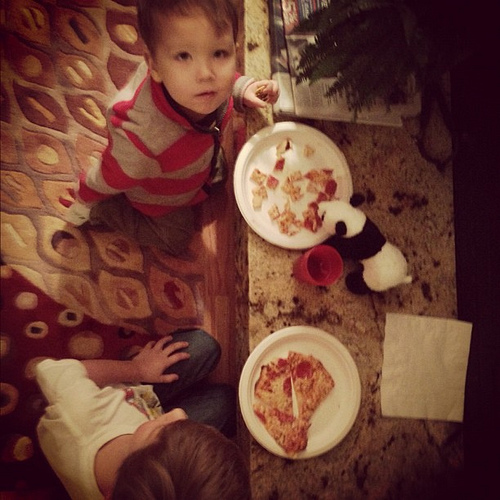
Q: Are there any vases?
A: No, there are no vases.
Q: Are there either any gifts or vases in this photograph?
A: No, there are no vases or gifts.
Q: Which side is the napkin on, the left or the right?
A: The napkin is on the right of the image.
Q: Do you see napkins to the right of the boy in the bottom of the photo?
A: Yes, there is a napkin to the right of the boy.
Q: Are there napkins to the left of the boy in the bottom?
A: No, the napkin is to the right of the boy.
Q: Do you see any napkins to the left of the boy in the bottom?
A: No, the napkin is to the right of the boy.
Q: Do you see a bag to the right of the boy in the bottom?
A: No, there is a napkin to the right of the boy.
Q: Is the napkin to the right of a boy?
A: Yes, the napkin is to the right of a boy.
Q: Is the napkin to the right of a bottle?
A: No, the napkin is to the right of a boy.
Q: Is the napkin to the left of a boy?
A: No, the napkin is to the right of a boy.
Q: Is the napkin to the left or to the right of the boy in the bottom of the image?
A: The napkin is to the right of the boy.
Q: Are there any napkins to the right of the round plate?
A: Yes, there is a napkin to the right of the plate.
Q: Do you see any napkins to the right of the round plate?
A: Yes, there is a napkin to the right of the plate.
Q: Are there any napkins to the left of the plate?
A: No, the napkin is to the right of the plate.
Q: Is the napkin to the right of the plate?
A: Yes, the napkin is to the right of the plate.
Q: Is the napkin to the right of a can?
A: No, the napkin is to the right of the plate.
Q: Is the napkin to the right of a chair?
A: No, the napkin is to the right of a pizza slice.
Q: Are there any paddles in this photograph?
A: No, there are no paddles.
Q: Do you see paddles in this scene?
A: No, there are no paddles.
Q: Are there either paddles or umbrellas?
A: No, there are no paddles or umbrellas.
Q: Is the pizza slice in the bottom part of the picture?
A: Yes, the pizza slice is in the bottom of the image.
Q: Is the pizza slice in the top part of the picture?
A: No, the pizza slice is in the bottom of the image.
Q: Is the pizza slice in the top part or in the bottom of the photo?
A: The pizza slice is in the bottom of the image.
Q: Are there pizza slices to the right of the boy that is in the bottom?
A: Yes, there is a pizza slice to the right of the boy.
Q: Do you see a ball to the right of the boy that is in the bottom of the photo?
A: No, there is a pizza slice to the right of the boy.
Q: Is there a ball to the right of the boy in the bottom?
A: No, there is a pizza slice to the right of the boy.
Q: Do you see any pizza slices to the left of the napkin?
A: Yes, there is a pizza slice to the left of the napkin.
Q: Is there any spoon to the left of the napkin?
A: No, there is a pizza slice to the left of the napkin.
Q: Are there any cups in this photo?
A: Yes, there is a cup.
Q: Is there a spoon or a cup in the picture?
A: Yes, there is a cup.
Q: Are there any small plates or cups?
A: Yes, there is a small cup.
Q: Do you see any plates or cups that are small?
A: Yes, the cup is small.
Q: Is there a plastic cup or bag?
A: Yes, there is a plastic cup.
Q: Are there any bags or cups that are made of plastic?
A: Yes, the cup is made of plastic.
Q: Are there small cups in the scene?
A: Yes, there is a small cup.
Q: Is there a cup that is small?
A: Yes, there is a cup that is small.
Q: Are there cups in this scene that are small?
A: Yes, there is a cup that is small.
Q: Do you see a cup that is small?
A: Yes, there is a cup that is small.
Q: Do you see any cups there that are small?
A: Yes, there is a cup that is small.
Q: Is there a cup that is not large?
A: Yes, there is a small cup.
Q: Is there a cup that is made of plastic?
A: Yes, there is a cup that is made of plastic.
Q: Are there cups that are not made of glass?
A: Yes, there is a cup that is made of plastic.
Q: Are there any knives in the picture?
A: No, there are no knives.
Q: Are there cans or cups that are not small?
A: No, there is a cup but it is small.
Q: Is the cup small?
A: Yes, the cup is small.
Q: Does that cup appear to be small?
A: Yes, the cup is small.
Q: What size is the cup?
A: The cup is small.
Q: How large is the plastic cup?
A: The cup is small.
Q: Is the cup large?
A: No, the cup is small.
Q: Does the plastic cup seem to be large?
A: No, the cup is small.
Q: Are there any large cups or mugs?
A: No, there is a cup but it is small.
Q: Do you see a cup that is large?
A: No, there is a cup but it is small.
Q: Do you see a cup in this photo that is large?
A: No, there is a cup but it is small.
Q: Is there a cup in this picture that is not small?
A: No, there is a cup but it is small.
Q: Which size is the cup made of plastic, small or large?
A: The cup is small.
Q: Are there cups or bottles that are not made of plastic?
A: No, there is a cup but it is made of plastic.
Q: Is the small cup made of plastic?
A: Yes, the cup is made of plastic.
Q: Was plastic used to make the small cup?
A: Yes, the cup is made of plastic.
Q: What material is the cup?
A: The cup is made of plastic.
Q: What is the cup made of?
A: The cup is made of plastic.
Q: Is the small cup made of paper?
A: No, the cup is made of plastic.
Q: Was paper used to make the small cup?
A: No, the cup is made of plastic.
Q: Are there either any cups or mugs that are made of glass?
A: No, there is a cup but it is made of plastic.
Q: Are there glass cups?
A: No, there is a cup but it is made of plastic.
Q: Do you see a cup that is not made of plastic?
A: No, there is a cup but it is made of plastic.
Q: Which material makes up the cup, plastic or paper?
A: The cup is made of plastic.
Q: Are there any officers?
A: No, there are no officers.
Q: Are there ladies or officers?
A: No, there are no officers or ladies.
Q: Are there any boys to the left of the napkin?
A: Yes, there is a boy to the left of the napkin.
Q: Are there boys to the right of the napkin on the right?
A: No, the boy is to the left of the napkin.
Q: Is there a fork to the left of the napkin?
A: No, there is a boy to the left of the napkin.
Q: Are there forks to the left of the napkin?
A: No, there is a boy to the left of the napkin.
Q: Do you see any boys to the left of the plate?
A: Yes, there is a boy to the left of the plate.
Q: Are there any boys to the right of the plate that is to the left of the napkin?
A: No, the boy is to the left of the plate.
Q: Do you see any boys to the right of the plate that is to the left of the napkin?
A: No, the boy is to the left of the plate.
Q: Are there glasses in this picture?
A: No, there are no glasses.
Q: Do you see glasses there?
A: No, there are no glasses.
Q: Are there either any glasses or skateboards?
A: No, there are no glasses or skateboards.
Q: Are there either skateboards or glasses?
A: No, there are no glasses or skateboards.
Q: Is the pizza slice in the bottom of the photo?
A: Yes, the pizza slice is in the bottom of the image.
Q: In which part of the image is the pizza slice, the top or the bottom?
A: The pizza slice is in the bottom of the image.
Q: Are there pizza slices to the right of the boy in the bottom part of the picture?
A: Yes, there is a pizza slice to the right of the boy.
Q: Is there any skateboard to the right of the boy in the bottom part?
A: No, there is a pizza slice to the right of the boy.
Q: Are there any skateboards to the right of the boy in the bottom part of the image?
A: No, there is a pizza slice to the right of the boy.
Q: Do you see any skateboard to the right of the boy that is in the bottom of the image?
A: No, there is a pizza slice to the right of the boy.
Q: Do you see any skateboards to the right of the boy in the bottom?
A: No, there is a pizza slice to the right of the boy.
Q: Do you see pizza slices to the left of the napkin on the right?
A: Yes, there is a pizza slice to the left of the napkin.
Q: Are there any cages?
A: No, there are no cages.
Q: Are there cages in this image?
A: No, there are no cages.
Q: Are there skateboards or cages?
A: No, there are no cages or skateboards.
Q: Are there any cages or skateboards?
A: No, there are no cages or skateboards.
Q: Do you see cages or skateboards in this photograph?
A: No, there are no cages or skateboards.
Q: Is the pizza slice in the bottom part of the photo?
A: Yes, the pizza slice is in the bottom of the image.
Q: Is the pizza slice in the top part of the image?
A: No, the pizza slice is in the bottom of the image.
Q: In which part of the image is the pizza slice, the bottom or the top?
A: The pizza slice is in the bottom of the image.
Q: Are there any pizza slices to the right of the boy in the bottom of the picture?
A: Yes, there is a pizza slice to the right of the boy.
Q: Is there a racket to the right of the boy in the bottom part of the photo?
A: No, there is a pizza slice to the right of the boy.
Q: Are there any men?
A: No, there are no men.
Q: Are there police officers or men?
A: No, there are no men or police officers.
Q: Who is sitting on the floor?
A: The boy is sitting on the floor.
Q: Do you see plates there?
A: Yes, there is a plate.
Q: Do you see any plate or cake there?
A: Yes, there is a plate.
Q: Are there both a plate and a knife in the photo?
A: No, there is a plate but no knives.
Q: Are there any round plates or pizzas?
A: Yes, there is a round plate.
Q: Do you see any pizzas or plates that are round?
A: Yes, the plate is round.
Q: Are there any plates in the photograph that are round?
A: Yes, there is a round plate.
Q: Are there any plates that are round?
A: Yes, there is a plate that is round.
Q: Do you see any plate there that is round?
A: Yes, there is a plate that is round.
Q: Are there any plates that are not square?
A: Yes, there is a round plate.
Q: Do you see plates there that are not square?
A: Yes, there is a round plate.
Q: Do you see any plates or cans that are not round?
A: No, there is a plate but it is round.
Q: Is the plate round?
A: Yes, the plate is round.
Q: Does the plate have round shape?
A: Yes, the plate is round.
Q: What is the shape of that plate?
A: The plate is round.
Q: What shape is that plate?
A: The plate is round.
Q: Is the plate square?
A: No, the plate is round.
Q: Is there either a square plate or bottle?
A: No, there is a plate but it is round.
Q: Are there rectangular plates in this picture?
A: No, there is a plate but it is round.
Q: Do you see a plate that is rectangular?
A: No, there is a plate but it is round.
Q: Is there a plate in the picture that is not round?
A: No, there is a plate but it is round.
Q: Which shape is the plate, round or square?
A: The plate is round.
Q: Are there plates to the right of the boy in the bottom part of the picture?
A: Yes, there is a plate to the right of the boy.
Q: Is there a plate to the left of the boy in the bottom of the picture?
A: No, the plate is to the right of the boy.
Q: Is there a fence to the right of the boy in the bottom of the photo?
A: No, there is a plate to the right of the boy.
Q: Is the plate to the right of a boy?
A: Yes, the plate is to the right of a boy.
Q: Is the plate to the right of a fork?
A: No, the plate is to the right of a boy.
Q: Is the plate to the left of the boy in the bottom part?
A: No, the plate is to the right of the boy.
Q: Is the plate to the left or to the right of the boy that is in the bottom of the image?
A: The plate is to the right of the boy.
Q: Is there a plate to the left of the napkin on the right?
A: Yes, there is a plate to the left of the napkin.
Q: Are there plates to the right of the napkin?
A: No, the plate is to the left of the napkin.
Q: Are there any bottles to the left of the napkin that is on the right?
A: No, there is a plate to the left of the napkin.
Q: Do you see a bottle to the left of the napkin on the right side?
A: No, there is a plate to the left of the napkin.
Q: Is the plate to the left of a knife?
A: No, the plate is to the left of a napkin.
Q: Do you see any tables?
A: Yes, there is a table.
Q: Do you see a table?
A: Yes, there is a table.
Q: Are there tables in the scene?
A: Yes, there is a table.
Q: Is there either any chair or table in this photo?
A: Yes, there is a table.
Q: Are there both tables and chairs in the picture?
A: No, there is a table but no chairs.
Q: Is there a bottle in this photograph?
A: No, there are no bottles.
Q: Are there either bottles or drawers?
A: No, there are no bottles or drawers.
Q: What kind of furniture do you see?
A: The furniture is a table.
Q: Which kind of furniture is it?
A: The piece of furniture is a table.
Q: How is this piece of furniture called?
A: That is a table.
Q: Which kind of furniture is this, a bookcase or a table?
A: That is a table.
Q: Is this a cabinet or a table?
A: This is a table.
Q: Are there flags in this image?
A: No, there are no flags.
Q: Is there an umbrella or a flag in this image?
A: No, there are no flags or umbrellas.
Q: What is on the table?
A: The plant is on the table.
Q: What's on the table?
A: The plant is on the table.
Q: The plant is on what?
A: The plant is on the table.